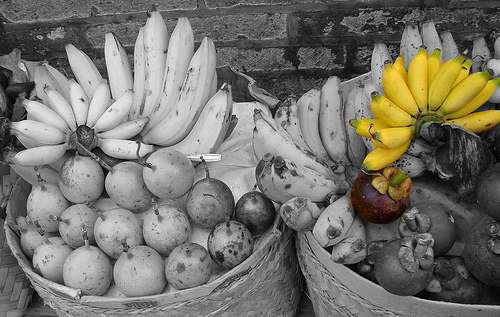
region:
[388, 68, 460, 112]
bananas are yellow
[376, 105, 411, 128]
the peel on the banana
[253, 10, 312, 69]
a brick wall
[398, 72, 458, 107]
the fruit is yellow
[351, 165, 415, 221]
deep red fruit with a green stem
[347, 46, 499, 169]
bunch of yellow bananas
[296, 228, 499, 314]
woven grass produce basket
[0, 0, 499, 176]
dirty brick wall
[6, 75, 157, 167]
bunch of bananas shown in black and white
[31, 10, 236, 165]
bunch of bananas shown in black and white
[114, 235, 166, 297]
round fruit shown in black and white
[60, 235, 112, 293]
round fruit shown in black and white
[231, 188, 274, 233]
round fruit shown in black and white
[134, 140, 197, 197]
This is a passion fruit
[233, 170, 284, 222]
This is a passion fruit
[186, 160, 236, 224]
This is a passion fruit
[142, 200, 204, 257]
This is a passion fruit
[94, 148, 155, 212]
This is a passion fruit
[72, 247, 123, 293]
This is a passion fruit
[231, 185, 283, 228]
This is a passion fruit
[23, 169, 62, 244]
This is a passion fruit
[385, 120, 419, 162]
a yellow banana in basket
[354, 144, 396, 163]
a yellow banana in basket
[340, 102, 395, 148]
a yellow banana in basket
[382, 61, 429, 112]
a yellow banana in basket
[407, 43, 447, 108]
a yellow banana in basket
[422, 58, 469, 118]
a yellow banana in basket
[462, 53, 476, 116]
a yellow banana in basket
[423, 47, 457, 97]
a yellow banana in basket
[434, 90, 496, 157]
a yellow banana in basket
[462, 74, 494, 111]
a yellow banana in basket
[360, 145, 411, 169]
yellow banana in bunch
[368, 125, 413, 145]
yellow banana in bunch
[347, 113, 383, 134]
yellow banana in bunch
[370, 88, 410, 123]
yellow banana in bunch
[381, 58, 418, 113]
yellow banana in bunch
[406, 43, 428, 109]
yellow banana in bunch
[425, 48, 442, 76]
yellow banana in bunch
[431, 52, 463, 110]
yellow banana in bunch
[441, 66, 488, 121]
yellow banana in bunch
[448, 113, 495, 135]
yellow banana in bunch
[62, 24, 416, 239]
these are fruits and veggies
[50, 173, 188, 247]
the fruits are round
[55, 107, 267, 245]
these are bananas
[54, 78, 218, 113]
the bananas are in bunches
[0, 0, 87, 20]
a brick in a wall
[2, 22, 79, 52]
a brick in a wall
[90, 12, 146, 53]
a brick in a wall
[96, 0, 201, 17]
a brick in a wall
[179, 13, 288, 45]
a brick in a wall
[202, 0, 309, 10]
a brick in a wall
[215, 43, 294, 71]
a brick in a wall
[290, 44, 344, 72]
a brick in a wall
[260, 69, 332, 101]
a brick in a wall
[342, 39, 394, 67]
a brick in a wall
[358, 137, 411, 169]
a ripe yellow banana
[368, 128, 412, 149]
a ripe yellow banana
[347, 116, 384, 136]
a ripe yellow banana